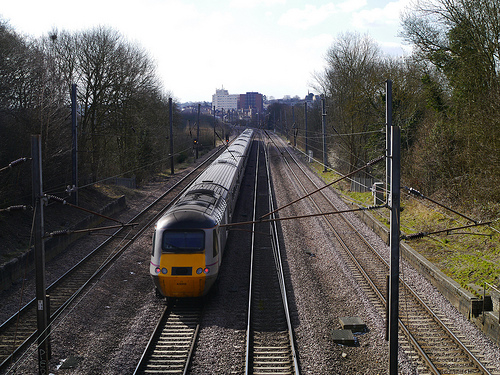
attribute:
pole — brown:
[382, 77, 403, 373]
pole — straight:
[68, 81, 81, 208]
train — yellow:
[140, 126, 258, 308]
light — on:
[184, 128, 209, 151]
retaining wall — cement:
[30, 171, 123, 271]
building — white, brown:
[237, 92, 264, 129]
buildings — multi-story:
[211, 86, 277, 126]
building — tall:
[208, 81, 256, 118]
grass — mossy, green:
[293, 131, 499, 312]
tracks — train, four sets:
[0, 124, 497, 372]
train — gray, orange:
[148, 126, 253, 304]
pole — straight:
[343, 111, 424, 308]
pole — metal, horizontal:
[233, 82, 494, 374]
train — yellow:
[145, 116, 255, 300]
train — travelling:
[152, 117, 280, 301]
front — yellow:
[134, 239, 239, 309]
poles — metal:
[360, 140, 410, 287]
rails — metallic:
[1, 128, 494, 373]